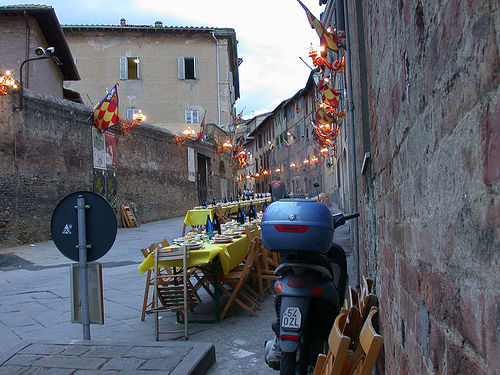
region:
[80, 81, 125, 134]
multicolored flag on the stone wall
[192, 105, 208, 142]
multicolored flag on the stone wall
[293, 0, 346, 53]
multicolored flag on the stone wall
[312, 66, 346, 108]
multicolored flag on the stone wall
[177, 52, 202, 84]
window with shutters on a building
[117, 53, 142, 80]
window with shutters on a building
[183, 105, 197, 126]
window with shutters on a building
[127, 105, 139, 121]
window with shutters on a building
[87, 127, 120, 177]
poster hanging on a stone wall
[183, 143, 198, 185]
poster hanging on a stone wall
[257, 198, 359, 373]
a gray colored motorcycle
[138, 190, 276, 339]
two tables with chairs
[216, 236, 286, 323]
brown wooden chairs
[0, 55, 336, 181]
orange colored lights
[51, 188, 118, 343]
back of signs on a metal post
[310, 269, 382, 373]
folded chairs against the wall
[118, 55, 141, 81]
an illuminated light in the window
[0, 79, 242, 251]
a concrete wall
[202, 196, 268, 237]
blue bottles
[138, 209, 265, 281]
a yellow table cloth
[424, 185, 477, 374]
An old brick wall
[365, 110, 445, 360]
An old brick wall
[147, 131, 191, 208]
An old brick wall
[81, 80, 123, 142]
A umbrella decoration on a wall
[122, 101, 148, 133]
A umbrella decoration on a wall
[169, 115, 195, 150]
A umbrella decoration on a wall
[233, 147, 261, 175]
A umbrella decoration on a wall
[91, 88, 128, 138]
red and yellow flag on the wall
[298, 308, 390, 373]
chairs leaning against the wall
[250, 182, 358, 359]
vespa parked by the wall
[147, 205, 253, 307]
table set with a yellow table cloth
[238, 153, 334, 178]
lights along the wall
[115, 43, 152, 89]
window with a light on inside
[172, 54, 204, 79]
shutters open on the dark window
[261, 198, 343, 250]
box on the back of the vespa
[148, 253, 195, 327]
chair leaning against the end of the table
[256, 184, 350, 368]
bike parked by a wall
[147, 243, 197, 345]
folded chair by a table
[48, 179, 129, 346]
back of sign on a pole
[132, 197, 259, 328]
tables and chairs in the road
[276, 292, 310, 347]
license plate on bike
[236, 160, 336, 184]
lights on a building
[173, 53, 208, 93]
window on a building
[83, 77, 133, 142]
flag on a wall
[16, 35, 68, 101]
street lights on a wall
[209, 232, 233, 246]
plates on a table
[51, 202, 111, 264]
sign on the pole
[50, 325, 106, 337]
pole on the ground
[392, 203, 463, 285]
the wall is brick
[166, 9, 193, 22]
clouds in the sky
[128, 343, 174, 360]
brick on the platform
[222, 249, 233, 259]
the tablecloth is yellow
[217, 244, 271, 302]
chairs at the table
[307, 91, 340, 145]
lights on the wall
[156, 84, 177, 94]
the building is tan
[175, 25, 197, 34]
roof of the building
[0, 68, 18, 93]
white lights on wall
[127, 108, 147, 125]
white lights on wall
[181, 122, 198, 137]
white lights on wall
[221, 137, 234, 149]
white lights on wall